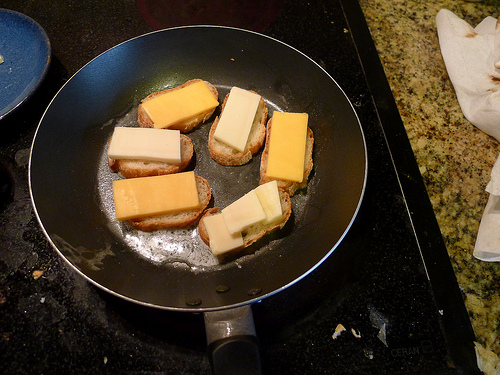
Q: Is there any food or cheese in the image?
A: Yes, there is cheese.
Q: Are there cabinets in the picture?
A: No, there are no cabinets.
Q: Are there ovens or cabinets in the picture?
A: No, there are no cabinets or ovens.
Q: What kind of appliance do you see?
A: The appliance is a stove.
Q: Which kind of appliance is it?
A: The appliance is a stove.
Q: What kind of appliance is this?
A: That is a stove.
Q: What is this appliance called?
A: That is a stove.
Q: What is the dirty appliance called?
A: The appliance is a stove.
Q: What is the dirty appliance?
A: The appliance is a stove.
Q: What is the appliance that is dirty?
A: The appliance is a stove.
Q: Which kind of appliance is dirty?
A: The appliance is a stove.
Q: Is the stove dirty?
A: Yes, the stove is dirty.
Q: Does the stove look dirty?
A: Yes, the stove is dirty.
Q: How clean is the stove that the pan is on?
A: The stove is dirty.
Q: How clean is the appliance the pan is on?
A: The stove is dirty.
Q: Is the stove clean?
A: No, the stove is dirty.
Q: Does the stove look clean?
A: No, the stove is dirty.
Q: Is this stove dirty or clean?
A: The stove is dirty.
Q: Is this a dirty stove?
A: Yes, this is a dirty stove.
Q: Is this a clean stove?
A: No, this is a dirty stove.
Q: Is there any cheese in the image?
A: Yes, there is cheese.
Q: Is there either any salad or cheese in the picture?
A: Yes, there is cheese.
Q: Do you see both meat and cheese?
A: No, there is cheese but no meat.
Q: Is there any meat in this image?
A: No, there is no meat.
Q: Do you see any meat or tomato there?
A: No, there are no meat or tomatoes.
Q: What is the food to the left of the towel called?
A: The food is cheese.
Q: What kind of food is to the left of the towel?
A: The food is cheese.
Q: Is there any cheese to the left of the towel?
A: Yes, there is cheese to the left of the towel.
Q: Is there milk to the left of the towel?
A: No, there is cheese to the left of the towel.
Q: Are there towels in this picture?
A: Yes, there is a towel.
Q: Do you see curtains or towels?
A: Yes, there is a towel.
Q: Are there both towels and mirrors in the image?
A: No, there is a towel but no mirrors.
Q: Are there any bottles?
A: No, there are no bottles.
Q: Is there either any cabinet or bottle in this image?
A: No, there are no bottles or cabinets.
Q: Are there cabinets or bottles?
A: No, there are no bottles or cabinets.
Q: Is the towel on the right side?
A: Yes, the towel is on the right of the image.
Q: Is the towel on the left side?
A: No, the towel is on the right of the image.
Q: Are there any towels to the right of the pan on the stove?
A: Yes, there is a towel to the right of the pan.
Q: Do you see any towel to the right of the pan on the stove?
A: Yes, there is a towel to the right of the pan.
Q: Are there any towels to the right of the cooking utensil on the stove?
A: Yes, there is a towel to the right of the pan.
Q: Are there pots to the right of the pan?
A: No, there is a towel to the right of the pan.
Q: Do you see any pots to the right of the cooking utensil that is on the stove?
A: No, there is a towel to the right of the pan.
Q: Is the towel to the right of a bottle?
A: No, the towel is to the right of a pan.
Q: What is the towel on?
A: The towel is on the counter.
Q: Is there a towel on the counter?
A: Yes, there is a towel on the counter.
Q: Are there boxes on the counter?
A: No, there is a towel on the counter.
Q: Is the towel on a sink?
A: No, the towel is on a counter.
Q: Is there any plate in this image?
A: Yes, there is a plate.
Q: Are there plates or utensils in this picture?
A: Yes, there is a plate.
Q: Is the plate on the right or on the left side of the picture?
A: The plate is on the left of the image.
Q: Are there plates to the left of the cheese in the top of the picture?
A: Yes, there is a plate to the left of the cheese.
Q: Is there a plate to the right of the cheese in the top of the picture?
A: No, the plate is to the left of the cheese.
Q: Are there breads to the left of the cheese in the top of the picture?
A: No, there is a plate to the left of the cheese.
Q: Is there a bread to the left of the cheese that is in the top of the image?
A: No, there is a plate to the left of the cheese.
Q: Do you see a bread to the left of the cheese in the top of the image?
A: No, there is a plate to the left of the cheese.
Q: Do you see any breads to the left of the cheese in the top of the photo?
A: No, there is a plate to the left of the cheese.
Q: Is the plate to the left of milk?
A: No, the plate is to the left of the cheese.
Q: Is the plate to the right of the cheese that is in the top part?
A: No, the plate is to the left of the cheese.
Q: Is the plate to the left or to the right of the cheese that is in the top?
A: The plate is to the left of the cheese.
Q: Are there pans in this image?
A: Yes, there is a pan.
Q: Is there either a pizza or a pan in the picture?
A: Yes, there is a pan.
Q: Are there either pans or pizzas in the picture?
A: Yes, there is a pan.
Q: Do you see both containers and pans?
A: No, there is a pan but no containers.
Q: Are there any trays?
A: No, there are no trays.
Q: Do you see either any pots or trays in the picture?
A: No, there are no trays or pots.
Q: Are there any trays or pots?
A: No, there are no trays or pots.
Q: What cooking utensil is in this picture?
A: The cooking utensil is a pan.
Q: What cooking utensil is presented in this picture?
A: The cooking utensil is a pan.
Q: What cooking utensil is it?
A: The cooking utensil is a pan.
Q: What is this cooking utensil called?
A: That is a pan.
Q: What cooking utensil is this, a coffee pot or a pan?
A: That is a pan.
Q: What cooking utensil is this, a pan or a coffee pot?
A: That is a pan.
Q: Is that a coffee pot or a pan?
A: That is a pan.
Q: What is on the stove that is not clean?
A: The pan is on the stove.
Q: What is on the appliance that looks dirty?
A: The pan is on the stove.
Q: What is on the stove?
A: The pan is on the stove.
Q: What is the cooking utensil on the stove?
A: The cooking utensil is a pan.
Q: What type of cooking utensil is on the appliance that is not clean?
A: The cooking utensil is a pan.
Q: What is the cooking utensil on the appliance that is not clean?
A: The cooking utensil is a pan.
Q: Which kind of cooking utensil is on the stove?
A: The cooking utensil is a pan.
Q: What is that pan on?
A: The pan is on the stove.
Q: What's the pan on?
A: The pan is on the stove.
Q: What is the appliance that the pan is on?
A: The appliance is a stove.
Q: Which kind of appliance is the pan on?
A: The pan is on the stove.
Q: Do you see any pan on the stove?
A: Yes, there is a pan on the stove.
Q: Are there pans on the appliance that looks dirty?
A: Yes, there is a pan on the stove.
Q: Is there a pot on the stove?
A: No, there is a pan on the stove.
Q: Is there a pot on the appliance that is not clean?
A: No, there is a pan on the stove.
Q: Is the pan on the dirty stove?
A: Yes, the pan is on the stove.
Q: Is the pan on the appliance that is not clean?
A: Yes, the pan is on the stove.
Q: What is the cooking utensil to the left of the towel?
A: The cooking utensil is a pan.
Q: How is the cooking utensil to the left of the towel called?
A: The cooking utensil is a pan.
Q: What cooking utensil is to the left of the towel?
A: The cooking utensil is a pan.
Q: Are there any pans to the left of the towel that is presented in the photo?
A: Yes, there is a pan to the left of the towel.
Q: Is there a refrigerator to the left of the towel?
A: No, there is a pan to the left of the towel.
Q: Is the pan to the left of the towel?
A: Yes, the pan is to the left of the towel.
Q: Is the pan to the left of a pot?
A: No, the pan is to the left of the towel.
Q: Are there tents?
A: No, there are no tents.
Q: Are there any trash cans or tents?
A: No, there are no tents or trash cans.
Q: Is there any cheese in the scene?
A: Yes, there is cheese.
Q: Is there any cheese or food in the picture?
A: Yes, there is cheese.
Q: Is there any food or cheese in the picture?
A: Yes, there is cheese.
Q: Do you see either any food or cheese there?
A: Yes, there is cheese.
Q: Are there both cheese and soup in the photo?
A: No, there is cheese but no soup.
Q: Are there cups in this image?
A: No, there are no cups.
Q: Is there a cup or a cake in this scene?
A: No, there are no cups or cakes.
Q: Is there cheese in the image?
A: Yes, there is cheese.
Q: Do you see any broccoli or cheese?
A: Yes, there is cheese.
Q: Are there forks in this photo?
A: No, there are no forks.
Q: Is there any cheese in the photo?
A: Yes, there is cheese.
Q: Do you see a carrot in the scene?
A: No, there are no carrots.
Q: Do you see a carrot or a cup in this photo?
A: No, there are no carrots or cups.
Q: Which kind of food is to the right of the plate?
A: The food is cheese.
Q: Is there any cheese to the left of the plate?
A: No, the cheese is to the right of the plate.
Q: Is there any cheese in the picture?
A: Yes, there is cheese.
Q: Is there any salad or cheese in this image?
A: Yes, there is cheese.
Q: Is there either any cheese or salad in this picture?
A: Yes, there is cheese.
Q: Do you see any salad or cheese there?
A: Yes, there is cheese.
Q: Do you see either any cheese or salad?
A: Yes, there is cheese.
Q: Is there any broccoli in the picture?
A: No, there is no broccoli.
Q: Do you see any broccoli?
A: No, there is no broccoli.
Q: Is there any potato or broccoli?
A: No, there are no broccoli or potatoes.